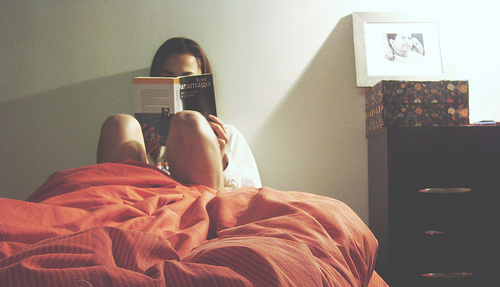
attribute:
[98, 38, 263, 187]
woman — reading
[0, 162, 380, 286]
comforter — orange, red, disheveled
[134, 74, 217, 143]
book — opened, paperback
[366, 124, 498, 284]
dresser — black, rectangular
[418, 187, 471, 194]
handle — silver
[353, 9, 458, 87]
picture — framed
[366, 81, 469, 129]
box — floral, multi-colored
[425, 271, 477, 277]
handle — silver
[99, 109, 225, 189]
knees — bent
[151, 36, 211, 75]
hair — brown